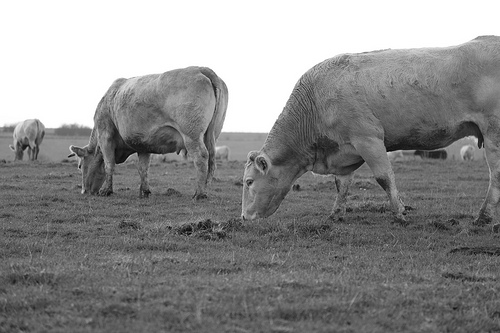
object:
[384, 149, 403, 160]
cows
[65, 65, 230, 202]
cow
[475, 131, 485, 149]
udders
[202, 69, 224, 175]
tail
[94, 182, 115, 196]
hoove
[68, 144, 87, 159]
ears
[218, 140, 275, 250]
trim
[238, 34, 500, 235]
cow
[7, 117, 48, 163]
cow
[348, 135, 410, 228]
legs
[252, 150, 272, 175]
ear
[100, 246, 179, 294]
grass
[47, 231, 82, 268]
sprigs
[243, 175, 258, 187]
eye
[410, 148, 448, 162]
cow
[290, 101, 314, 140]
wrinkles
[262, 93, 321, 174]
neck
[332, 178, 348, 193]
knee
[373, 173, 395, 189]
knee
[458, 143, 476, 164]
cow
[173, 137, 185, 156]
udder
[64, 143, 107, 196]
head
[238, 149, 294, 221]
head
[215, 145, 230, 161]
cow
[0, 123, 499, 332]
field